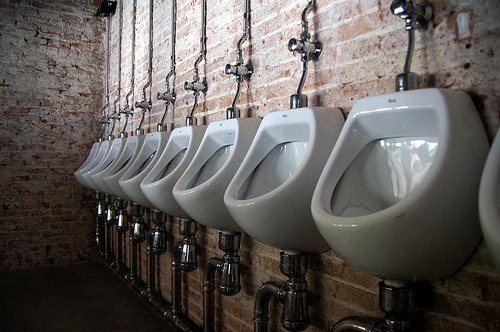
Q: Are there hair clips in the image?
A: No, there are no hair clips.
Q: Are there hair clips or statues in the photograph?
A: No, there are no hair clips or statues.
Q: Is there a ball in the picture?
A: No, there are no balls.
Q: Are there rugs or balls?
A: No, there are no balls or rugs.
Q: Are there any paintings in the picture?
A: No, there are no paintings.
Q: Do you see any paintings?
A: No, there are no paintings.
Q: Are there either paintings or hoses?
A: No, there are no paintings or hoses.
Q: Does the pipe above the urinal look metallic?
A: Yes, the pipe is metallic.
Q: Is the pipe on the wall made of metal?
A: Yes, the pipe is made of metal.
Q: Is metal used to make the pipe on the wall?
A: Yes, the pipe is made of metal.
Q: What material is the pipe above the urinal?
A: The pipe is made of metal.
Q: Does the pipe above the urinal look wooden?
A: No, the pipe is metallic.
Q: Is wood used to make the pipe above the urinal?
A: No, the pipe is made of metal.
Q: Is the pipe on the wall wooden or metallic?
A: The pipe is metallic.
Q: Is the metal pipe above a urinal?
A: Yes, the pipe is above a urinal.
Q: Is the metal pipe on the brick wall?
A: Yes, the pipe is on the wall.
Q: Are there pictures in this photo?
A: No, there are no pictures.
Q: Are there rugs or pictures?
A: No, there are no pictures or rugs.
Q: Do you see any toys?
A: No, there are no toys.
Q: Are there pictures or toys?
A: No, there are no toys or pictures.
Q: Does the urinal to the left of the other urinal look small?
A: Yes, the urinal is small.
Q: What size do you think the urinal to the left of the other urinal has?
A: The urinal has small size.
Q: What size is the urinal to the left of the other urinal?
A: The urinal is small.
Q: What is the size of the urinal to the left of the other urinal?
A: The urinal is small.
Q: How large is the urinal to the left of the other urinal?
A: The urinal is small.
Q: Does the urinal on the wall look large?
A: No, the urinal is small.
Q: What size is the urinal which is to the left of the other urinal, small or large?
A: The urinal is small.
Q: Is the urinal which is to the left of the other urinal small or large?
A: The urinal is small.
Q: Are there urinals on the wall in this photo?
A: Yes, there is a urinal on the wall.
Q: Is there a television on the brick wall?
A: No, there is a urinal on the wall.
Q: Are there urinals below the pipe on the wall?
A: Yes, there is a urinal below the pipe.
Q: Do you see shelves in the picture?
A: No, there are no shelves.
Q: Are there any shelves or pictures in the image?
A: No, there are no shelves or pictures.